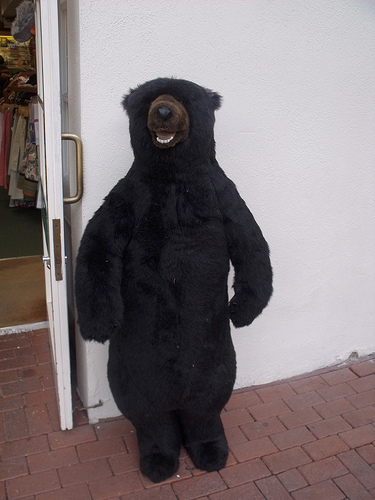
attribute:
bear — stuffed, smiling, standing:
[59, 70, 287, 484]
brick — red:
[247, 381, 347, 477]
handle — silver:
[53, 125, 106, 212]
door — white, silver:
[29, 6, 91, 433]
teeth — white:
[145, 121, 203, 155]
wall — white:
[256, 8, 370, 373]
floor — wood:
[4, 220, 54, 329]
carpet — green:
[0, 199, 45, 264]